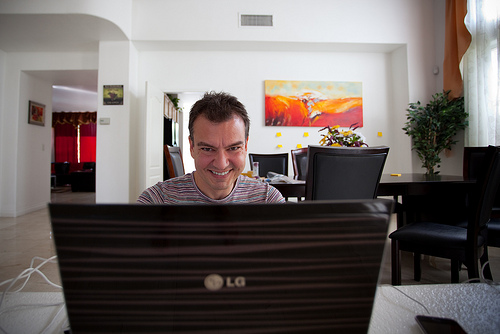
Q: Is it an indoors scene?
A: Yes, it is indoors.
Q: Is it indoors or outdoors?
A: It is indoors.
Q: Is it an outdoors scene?
A: No, it is indoors.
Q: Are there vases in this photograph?
A: No, there are no vases.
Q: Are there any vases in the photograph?
A: No, there are no vases.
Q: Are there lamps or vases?
A: No, there are no vases or lamps.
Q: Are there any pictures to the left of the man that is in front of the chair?
A: Yes, there is a picture to the left of the man.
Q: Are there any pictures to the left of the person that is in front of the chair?
A: Yes, there is a picture to the left of the man.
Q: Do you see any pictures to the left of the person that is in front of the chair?
A: Yes, there is a picture to the left of the man.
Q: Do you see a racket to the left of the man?
A: No, there is a picture to the left of the man.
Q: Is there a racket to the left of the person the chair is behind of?
A: No, there is a picture to the left of the man.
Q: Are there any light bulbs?
A: No, there are no light bulbs.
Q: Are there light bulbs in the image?
A: No, there are no light bulbs.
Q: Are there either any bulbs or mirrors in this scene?
A: No, there are no bulbs or mirrors.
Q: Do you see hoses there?
A: No, there are no hoses.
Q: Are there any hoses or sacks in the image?
A: No, there are no hoses or sacks.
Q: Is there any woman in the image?
A: No, there are no women.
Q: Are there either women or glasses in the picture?
A: No, there are no women or glasses.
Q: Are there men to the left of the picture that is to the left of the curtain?
A: Yes, there is a man to the left of the picture.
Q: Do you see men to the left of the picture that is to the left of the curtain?
A: Yes, there is a man to the left of the picture.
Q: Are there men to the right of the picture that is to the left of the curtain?
A: No, the man is to the left of the picture.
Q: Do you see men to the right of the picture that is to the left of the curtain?
A: No, the man is to the left of the picture.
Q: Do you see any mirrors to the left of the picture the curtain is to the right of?
A: No, there is a man to the left of the picture.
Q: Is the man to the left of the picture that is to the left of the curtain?
A: Yes, the man is to the left of the picture.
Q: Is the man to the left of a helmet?
A: No, the man is to the left of the picture.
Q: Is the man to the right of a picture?
A: No, the man is to the left of a picture.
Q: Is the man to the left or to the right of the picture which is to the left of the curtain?
A: The man is to the left of the picture.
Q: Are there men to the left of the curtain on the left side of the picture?
A: No, the man is to the right of the curtain.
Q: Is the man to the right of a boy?
A: No, the man is to the right of the curtain.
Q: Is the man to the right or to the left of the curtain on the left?
A: The man is to the right of the curtain.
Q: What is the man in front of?
A: The man is in front of the chair.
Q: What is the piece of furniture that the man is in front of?
A: The piece of furniture is a chair.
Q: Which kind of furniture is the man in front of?
A: The man is in front of the chair.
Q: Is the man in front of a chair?
A: Yes, the man is in front of a chair.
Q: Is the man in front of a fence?
A: No, the man is in front of a chair.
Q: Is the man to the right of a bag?
A: No, the man is to the right of a picture.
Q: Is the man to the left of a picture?
A: No, the man is to the right of a picture.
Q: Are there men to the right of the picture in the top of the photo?
A: Yes, there is a man to the right of the picture.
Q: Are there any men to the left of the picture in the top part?
A: No, the man is to the right of the picture.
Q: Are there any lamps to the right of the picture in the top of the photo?
A: No, there is a man to the right of the picture.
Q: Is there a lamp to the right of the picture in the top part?
A: No, there is a man to the right of the picture.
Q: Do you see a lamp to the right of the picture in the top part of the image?
A: No, there is a man to the right of the picture.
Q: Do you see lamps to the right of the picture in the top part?
A: No, there is a man to the right of the picture.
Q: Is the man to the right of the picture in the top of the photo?
A: Yes, the man is to the right of the picture.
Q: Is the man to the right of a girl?
A: No, the man is to the right of the picture.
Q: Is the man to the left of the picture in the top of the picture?
A: No, the man is to the right of the picture.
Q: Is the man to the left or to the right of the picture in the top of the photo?
A: The man is to the right of the picture.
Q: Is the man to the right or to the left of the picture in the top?
A: The man is to the right of the picture.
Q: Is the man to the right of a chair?
A: No, the man is to the left of a chair.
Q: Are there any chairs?
A: Yes, there is a chair.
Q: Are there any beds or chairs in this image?
A: Yes, there is a chair.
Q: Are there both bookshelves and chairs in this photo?
A: No, there is a chair but no bookshelves.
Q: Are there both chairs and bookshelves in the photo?
A: No, there is a chair but no bookshelves.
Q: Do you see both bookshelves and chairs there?
A: No, there is a chair but no bookshelves.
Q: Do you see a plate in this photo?
A: No, there are no plates.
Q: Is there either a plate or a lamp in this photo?
A: No, there are no plates or lamps.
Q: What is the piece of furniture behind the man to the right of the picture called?
A: The piece of furniture is a chair.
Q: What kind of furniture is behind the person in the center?
A: The piece of furniture is a chair.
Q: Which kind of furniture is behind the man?
A: The piece of furniture is a chair.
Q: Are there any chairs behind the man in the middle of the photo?
A: Yes, there is a chair behind the man.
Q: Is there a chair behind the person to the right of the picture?
A: Yes, there is a chair behind the man.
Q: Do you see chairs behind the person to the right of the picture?
A: Yes, there is a chair behind the man.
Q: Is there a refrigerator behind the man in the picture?
A: No, there is a chair behind the man.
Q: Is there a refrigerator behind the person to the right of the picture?
A: No, there is a chair behind the man.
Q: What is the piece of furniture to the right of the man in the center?
A: The piece of furniture is a chair.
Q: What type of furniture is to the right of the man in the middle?
A: The piece of furniture is a chair.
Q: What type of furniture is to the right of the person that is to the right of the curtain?
A: The piece of furniture is a chair.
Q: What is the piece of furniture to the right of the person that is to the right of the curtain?
A: The piece of furniture is a chair.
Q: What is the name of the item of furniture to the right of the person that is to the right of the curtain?
A: The piece of furniture is a chair.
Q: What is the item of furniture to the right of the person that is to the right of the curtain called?
A: The piece of furniture is a chair.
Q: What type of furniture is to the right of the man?
A: The piece of furniture is a chair.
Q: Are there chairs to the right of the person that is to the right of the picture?
A: Yes, there is a chair to the right of the man.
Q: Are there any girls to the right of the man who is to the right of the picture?
A: No, there is a chair to the right of the man.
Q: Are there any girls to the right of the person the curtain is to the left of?
A: No, there is a chair to the right of the man.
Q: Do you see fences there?
A: No, there are no fences.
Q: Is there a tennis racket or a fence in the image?
A: No, there are no fences or rackets.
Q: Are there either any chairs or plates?
A: Yes, there is a chair.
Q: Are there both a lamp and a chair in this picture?
A: No, there is a chair but no lamps.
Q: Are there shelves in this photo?
A: No, there are no shelves.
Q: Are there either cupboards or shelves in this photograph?
A: No, there are no shelves or cupboards.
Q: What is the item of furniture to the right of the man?
A: The piece of furniture is a chair.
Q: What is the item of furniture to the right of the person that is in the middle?
A: The piece of furniture is a chair.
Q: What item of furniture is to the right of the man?
A: The piece of furniture is a chair.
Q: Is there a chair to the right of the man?
A: Yes, there is a chair to the right of the man.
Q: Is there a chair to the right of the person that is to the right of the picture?
A: Yes, there is a chair to the right of the man.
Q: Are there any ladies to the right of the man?
A: No, there is a chair to the right of the man.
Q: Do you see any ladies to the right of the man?
A: No, there is a chair to the right of the man.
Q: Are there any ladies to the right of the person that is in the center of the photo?
A: No, there is a chair to the right of the man.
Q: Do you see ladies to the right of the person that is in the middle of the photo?
A: No, there is a chair to the right of the man.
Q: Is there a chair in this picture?
A: Yes, there is a chair.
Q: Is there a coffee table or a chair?
A: Yes, there is a chair.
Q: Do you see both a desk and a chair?
A: Yes, there are both a chair and a desk.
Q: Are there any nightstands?
A: No, there are no nightstands.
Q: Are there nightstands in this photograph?
A: No, there are no nightstands.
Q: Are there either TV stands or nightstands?
A: No, there are no nightstands or TV stands.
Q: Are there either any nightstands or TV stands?
A: No, there are no nightstands or TV stands.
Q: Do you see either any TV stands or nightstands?
A: No, there are no nightstands or TV stands.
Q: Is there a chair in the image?
A: Yes, there is a chair.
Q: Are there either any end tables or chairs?
A: Yes, there is a chair.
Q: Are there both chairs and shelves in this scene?
A: No, there is a chair but no shelves.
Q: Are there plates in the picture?
A: No, there are no plates.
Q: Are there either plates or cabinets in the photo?
A: No, there are no plates or cabinets.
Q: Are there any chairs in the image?
A: Yes, there is a chair.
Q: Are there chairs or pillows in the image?
A: Yes, there is a chair.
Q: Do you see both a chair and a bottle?
A: No, there is a chair but no bottles.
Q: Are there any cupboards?
A: No, there are no cupboards.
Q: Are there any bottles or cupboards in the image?
A: No, there are no cupboards or bottles.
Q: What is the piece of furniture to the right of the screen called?
A: The piece of furniture is a chair.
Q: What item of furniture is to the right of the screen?
A: The piece of furniture is a chair.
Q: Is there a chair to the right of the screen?
A: Yes, there is a chair to the right of the screen.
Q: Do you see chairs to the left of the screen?
A: No, the chair is to the right of the screen.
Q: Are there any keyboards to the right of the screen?
A: No, there is a chair to the right of the screen.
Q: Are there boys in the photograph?
A: No, there are no boys.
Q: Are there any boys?
A: No, there are no boys.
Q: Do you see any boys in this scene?
A: No, there are no boys.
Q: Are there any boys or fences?
A: No, there are no boys or fences.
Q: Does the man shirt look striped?
A: Yes, the shirt is striped.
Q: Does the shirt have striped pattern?
A: Yes, the shirt is striped.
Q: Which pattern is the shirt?
A: The shirt is striped.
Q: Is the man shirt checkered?
A: No, the shirt is striped.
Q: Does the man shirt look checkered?
A: No, the shirt is striped.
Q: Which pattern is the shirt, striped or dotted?
A: The shirt is striped.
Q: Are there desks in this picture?
A: Yes, there is a desk.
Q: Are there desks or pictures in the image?
A: Yes, there is a desk.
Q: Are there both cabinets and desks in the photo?
A: No, there is a desk but no cabinets.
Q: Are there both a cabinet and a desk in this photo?
A: No, there is a desk but no cabinets.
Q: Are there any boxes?
A: No, there are no boxes.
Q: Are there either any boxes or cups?
A: No, there are no boxes or cups.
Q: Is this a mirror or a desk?
A: This is a desk.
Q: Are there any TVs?
A: No, there are no tvs.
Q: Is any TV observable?
A: No, there are no televisions.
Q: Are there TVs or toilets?
A: No, there are no TVs or toilets.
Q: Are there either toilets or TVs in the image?
A: No, there are no TVs or toilets.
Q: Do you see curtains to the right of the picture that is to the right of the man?
A: Yes, there is a curtain to the right of the picture.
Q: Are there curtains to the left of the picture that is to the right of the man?
A: No, the curtain is to the right of the picture.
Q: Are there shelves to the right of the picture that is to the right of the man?
A: No, there is a curtain to the right of the picture.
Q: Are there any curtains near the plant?
A: Yes, there is a curtain near the plant.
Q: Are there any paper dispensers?
A: No, there are no paper dispensers.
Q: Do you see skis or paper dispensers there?
A: No, there are no paper dispensers or skis.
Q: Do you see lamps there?
A: No, there are no lamps.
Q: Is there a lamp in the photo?
A: No, there are no lamps.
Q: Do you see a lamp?
A: No, there are no lamps.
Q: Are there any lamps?
A: No, there are no lamps.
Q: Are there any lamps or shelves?
A: No, there are no lamps or shelves.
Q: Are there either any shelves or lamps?
A: No, there are no lamps or shelves.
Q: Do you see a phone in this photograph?
A: Yes, there is a phone.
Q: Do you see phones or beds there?
A: Yes, there is a phone.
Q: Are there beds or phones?
A: Yes, there is a phone.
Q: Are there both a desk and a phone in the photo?
A: Yes, there are both a phone and a desk.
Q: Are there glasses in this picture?
A: No, there are no glasses.